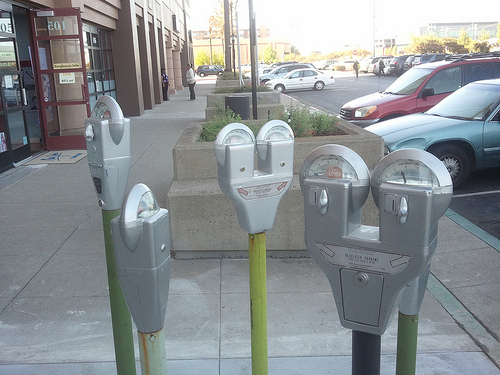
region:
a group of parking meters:
[83, 95, 452, 373]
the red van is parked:
[337, 54, 499, 129]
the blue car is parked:
[364, 78, 499, 190]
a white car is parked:
[265, 66, 337, 91]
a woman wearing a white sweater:
[185, 62, 198, 102]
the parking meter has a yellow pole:
[245, 229, 271, 374]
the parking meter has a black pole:
[351, 328, 380, 373]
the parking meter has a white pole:
[138, 328, 168, 373]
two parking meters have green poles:
[102, 209, 417, 374]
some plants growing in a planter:
[196, 99, 338, 140]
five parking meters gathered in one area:
[82, 91, 448, 374]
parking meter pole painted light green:
[242, 226, 277, 373]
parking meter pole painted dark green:
[101, 203, 133, 374]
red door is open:
[27, 8, 104, 155]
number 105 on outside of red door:
[48, 20, 68, 32]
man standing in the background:
[186, 67, 196, 101]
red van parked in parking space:
[341, 56, 498, 136]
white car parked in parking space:
[261, 63, 339, 93]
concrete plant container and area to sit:
[167, 115, 394, 255]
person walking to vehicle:
[352, 61, 359, 78]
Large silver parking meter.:
[72, 94, 142, 210]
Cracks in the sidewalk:
[12, 222, 114, 372]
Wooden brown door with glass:
[24, 9, 99, 149]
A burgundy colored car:
[318, 58, 485, 118]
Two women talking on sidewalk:
[151, 62, 218, 114]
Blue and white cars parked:
[264, 67, 336, 99]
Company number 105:
[38, 15, 71, 45]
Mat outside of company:
[27, 135, 92, 175]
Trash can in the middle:
[220, 72, 262, 129]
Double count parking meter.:
[288, 115, 424, 373]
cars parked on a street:
[331, 41, 498, 198]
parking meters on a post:
[204, 108, 299, 248]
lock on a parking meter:
[349, 267, 373, 291]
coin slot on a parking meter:
[381, 190, 401, 222]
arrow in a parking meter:
[394, 165, 414, 190]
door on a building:
[22, 2, 104, 158]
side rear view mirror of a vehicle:
[414, 85, 439, 106]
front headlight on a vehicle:
[351, 99, 383, 122]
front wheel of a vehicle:
[422, 131, 481, 191]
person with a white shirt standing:
[176, 57, 206, 104]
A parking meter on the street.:
[138, 124, 378, 192]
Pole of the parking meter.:
[234, 214, 378, 336]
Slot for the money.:
[298, 168, 368, 228]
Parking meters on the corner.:
[198, 75, 472, 374]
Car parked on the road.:
[321, 34, 484, 155]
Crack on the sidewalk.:
[41, 220, 89, 283]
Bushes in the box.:
[213, 82, 410, 188]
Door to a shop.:
[29, 8, 99, 158]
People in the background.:
[149, 58, 215, 107]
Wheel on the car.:
[409, 108, 486, 202]